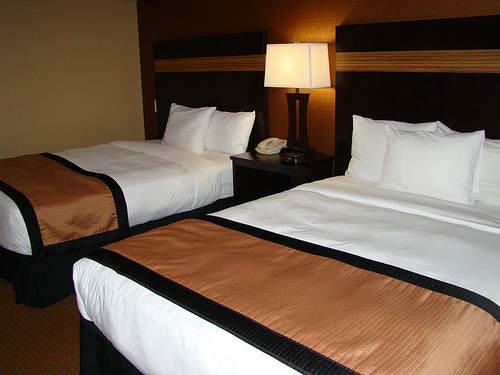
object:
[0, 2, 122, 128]
wall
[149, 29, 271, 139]
headboard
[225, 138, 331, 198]
night stand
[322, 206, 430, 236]
sheets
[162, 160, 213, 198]
sheets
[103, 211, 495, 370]
runner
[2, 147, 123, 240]
runner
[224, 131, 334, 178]
bedstand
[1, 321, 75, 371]
floor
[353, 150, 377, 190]
ground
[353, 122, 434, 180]
pillow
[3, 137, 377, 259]
white sheets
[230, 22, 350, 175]
lamp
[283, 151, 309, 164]
alarm clock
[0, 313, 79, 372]
carpet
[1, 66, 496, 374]
two beds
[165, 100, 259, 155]
pillows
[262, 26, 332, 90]
lamp shade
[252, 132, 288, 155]
phone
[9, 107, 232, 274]
bed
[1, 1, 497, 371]
bedroom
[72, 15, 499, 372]
bed